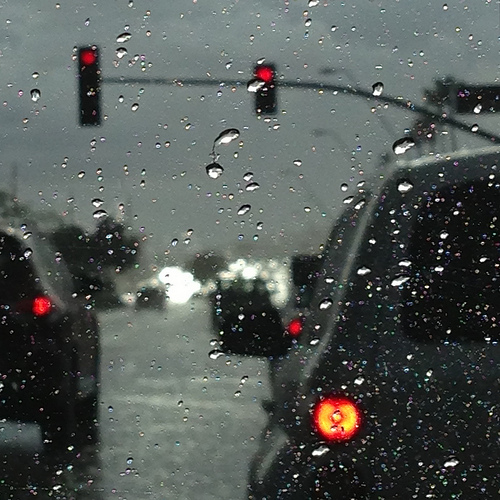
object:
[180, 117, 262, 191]
rain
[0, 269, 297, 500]
highway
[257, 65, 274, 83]
traffic light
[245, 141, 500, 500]
car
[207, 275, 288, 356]
car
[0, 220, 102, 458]
car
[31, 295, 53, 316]
lights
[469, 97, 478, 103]
trees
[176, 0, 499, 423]
background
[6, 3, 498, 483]
scene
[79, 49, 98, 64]
lights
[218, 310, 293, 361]
side mirror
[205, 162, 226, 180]
rain drops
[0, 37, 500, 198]
rainy sky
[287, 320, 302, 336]
headlights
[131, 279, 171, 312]
distance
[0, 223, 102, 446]
side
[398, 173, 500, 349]
window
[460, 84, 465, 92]
tree tops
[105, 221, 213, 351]
distant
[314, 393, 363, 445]
brake lights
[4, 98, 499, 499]
traffic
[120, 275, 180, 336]
forward